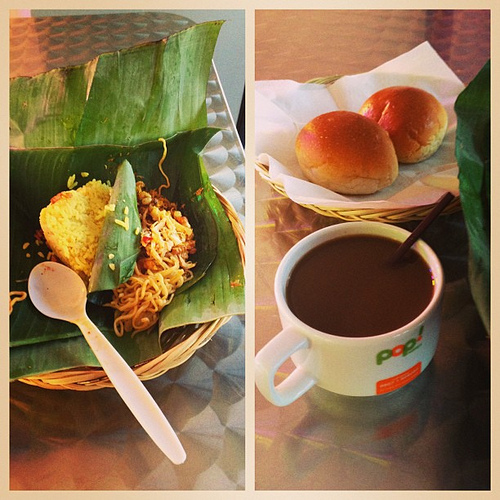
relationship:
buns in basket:
[298, 86, 450, 195] [327, 205, 428, 224]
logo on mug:
[375, 334, 418, 364] [258, 221, 444, 411]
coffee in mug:
[300, 250, 420, 321] [258, 221, 444, 411]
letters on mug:
[375, 338, 416, 369] [258, 221, 444, 411]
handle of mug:
[254, 328, 309, 415] [258, 221, 444, 411]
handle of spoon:
[80, 323, 186, 464] [28, 261, 186, 463]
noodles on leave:
[111, 208, 190, 332] [13, 20, 222, 160]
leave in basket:
[10, 332, 80, 371] [28, 371, 107, 391]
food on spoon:
[43, 262, 55, 272] [28, 261, 186, 463]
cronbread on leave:
[37, 181, 101, 273] [13, 20, 222, 160]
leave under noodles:
[8, 157, 33, 280] [111, 208, 190, 332]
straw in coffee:
[399, 194, 454, 257] [300, 250, 420, 321]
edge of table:
[142, 9, 201, 25] [10, 18, 184, 36]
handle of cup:
[254, 328, 309, 415] [258, 221, 444, 411]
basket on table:
[327, 205, 428, 224] [260, 426, 491, 492]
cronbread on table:
[37, 181, 117, 273] [10, 18, 184, 36]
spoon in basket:
[28, 261, 186, 463] [28, 371, 107, 391]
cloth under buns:
[256, 78, 294, 196] [298, 86, 450, 195]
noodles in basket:
[111, 176, 200, 333] [28, 371, 107, 391]